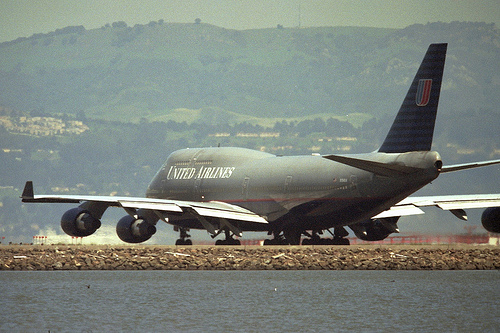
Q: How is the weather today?
A: It is clear.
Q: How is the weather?
A: It is clear.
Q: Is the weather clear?
A: Yes, it is clear.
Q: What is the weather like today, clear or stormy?
A: It is clear.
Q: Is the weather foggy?
A: No, it is clear.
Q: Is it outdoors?
A: Yes, it is outdoors.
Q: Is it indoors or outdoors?
A: It is outdoors.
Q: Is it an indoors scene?
A: No, it is outdoors.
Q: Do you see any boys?
A: No, there are no boys.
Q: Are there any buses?
A: No, there are no buses.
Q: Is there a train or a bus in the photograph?
A: No, there are no buses or trains.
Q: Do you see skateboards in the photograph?
A: No, there are no skateboards.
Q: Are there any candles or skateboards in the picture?
A: No, there are no skateboards or candles.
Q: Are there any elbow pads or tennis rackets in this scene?
A: No, there are no tennis rackets or elbow pads.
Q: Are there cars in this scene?
A: No, there are no cars.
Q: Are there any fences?
A: Yes, there is a fence.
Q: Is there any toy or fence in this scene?
A: Yes, there is a fence.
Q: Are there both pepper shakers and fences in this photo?
A: No, there is a fence but no pepper shakers.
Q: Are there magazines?
A: No, there are no magazines.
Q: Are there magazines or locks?
A: No, there are no magazines or locks.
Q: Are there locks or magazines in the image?
A: No, there are no magazines or locks.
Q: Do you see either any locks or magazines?
A: No, there are no magazines or locks.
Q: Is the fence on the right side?
A: Yes, the fence is on the right of the image.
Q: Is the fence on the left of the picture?
A: No, the fence is on the right of the image.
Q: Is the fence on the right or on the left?
A: The fence is on the right of the image.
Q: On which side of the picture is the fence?
A: The fence is on the right of the image.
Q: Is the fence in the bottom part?
A: Yes, the fence is in the bottom of the image.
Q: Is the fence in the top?
A: No, the fence is in the bottom of the image.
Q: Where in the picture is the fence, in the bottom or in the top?
A: The fence is in the bottom of the image.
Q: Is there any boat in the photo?
A: No, there are no boats.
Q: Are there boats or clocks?
A: No, there are no boats or clocks.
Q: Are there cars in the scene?
A: No, there are no cars.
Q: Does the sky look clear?
A: Yes, the sky is clear.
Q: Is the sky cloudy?
A: No, the sky is clear.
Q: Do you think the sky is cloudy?
A: No, the sky is clear.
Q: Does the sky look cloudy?
A: No, the sky is clear.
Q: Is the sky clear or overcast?
A: The sky is clear.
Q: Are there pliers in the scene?
A: No, there are no pliers.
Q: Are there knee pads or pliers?
A: No, there are no pliers or knee pads.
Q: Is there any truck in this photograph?
A: No, there are no trucks.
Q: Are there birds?
A: No, there are no birds.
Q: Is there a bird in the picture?
A: No, there are no birds.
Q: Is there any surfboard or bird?
A: No, there are no birds or surfboards.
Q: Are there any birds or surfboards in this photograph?
A: No, there are no birds or surfboards.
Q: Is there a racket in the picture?
A: No, there are no rackets.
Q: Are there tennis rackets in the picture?
A: No, there are no tennis rackets.